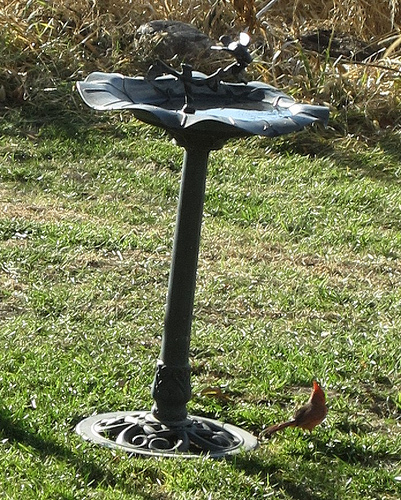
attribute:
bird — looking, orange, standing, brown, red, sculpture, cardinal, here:
[267, 378, 339, 444]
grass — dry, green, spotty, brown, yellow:
[42, 140, 116, 163]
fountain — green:
[97, 32, 274, 153]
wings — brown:
[297, 414, 319, 427]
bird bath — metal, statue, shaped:
[140, 87, 248, 131]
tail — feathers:
[255, 416, 297, 435]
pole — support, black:
[147, 184, 216, 230]